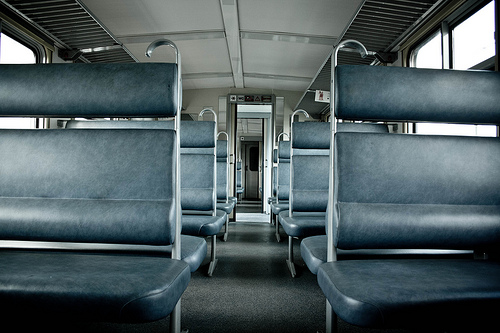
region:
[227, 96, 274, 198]
this is the door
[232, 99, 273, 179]
the door is open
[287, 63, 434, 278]
these are the seats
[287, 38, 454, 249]
these seats are empty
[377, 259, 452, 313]
the seat is leather like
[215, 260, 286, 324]
this is the floor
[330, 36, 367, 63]
the seat is metallic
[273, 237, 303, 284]
this is the leg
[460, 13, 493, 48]
this is the window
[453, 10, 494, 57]
the window is open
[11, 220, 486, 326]
inside of train car with dark gray floor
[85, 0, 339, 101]
vertical and horizontal lines going down center of ceiling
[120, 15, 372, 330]
metal curves on aisles separating front and back seats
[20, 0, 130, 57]
racks with metal slats across the frame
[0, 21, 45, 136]
window on the side with curved corners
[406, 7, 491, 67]
window with narrow upper panel and sliding panes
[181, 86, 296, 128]
beige wall at end of car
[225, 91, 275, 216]
silver doorway with sliding metal door with window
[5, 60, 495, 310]
rows of blue seats with head cushion above back cushion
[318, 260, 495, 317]
flat blue seats with rounded corners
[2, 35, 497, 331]
Seats with blue plastic like covering.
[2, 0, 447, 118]
Silver Metal Vents On Ceiling.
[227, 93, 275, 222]
Multi colored signs above door.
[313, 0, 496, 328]
Windows next to seating area.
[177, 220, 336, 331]
Grey Marbled Walk-Way.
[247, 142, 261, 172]
Window on door is dark.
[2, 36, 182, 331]
Silver metal pole on seat.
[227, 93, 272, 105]
Five signs in a row.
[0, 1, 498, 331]
Train car with several seats.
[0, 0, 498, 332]
Seating area in train.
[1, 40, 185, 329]
the seat frame is made of metal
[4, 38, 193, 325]
the seat frame is made of steel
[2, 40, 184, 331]
the frame is grey in color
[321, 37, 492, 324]
the frame is made of metal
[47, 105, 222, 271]
the frame is made of metal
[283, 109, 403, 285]
the frame is made of metal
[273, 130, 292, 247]
the frame is made of metal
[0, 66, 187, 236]
the backrest is made of plastic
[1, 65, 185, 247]
the plastic is grey in color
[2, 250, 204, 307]
the seat is made of plastic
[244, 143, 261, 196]
a white door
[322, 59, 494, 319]
a bluish gray seat on a train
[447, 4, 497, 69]
a window on a train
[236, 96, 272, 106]
signs on top of the doorway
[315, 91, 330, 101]
a white sign hanging from the ceiling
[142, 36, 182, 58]
a steel hook on top to the seat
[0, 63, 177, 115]
the head reast of the train seats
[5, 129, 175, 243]
the backrest of the train seat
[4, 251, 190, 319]
a blue bottom seat cushion for the train seat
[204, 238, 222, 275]
a metal fixture supporting the seats